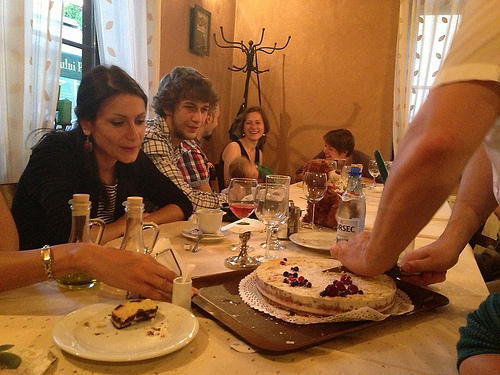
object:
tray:
[190, 266, 449, 352]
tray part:
[395, 278, 449, 314]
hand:
[47, 243, 199, 303]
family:
[1, 0, 500, 375]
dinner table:
[1, 172, 498, 375]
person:
[330, 0, 500, 287]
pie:
[256, 256, 397, 318]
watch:
[41, 244, 55, 281]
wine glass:
[254, 183, 289, 263]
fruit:
[283, 271, 312, 289]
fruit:
[320, 275, 364, 298]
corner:
[163, 3, 296, 182]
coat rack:
[213, 26, 292, 110]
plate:
[52, 298, 199, 362]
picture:
[197, 10, 209, 52]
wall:
[161, 3, 392, 167]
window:
[1, 0, 147, 182]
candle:
[56, 98, 72, 124]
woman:
[10, 64, 193, 251]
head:
[74, 65, 148, 164]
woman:
[219, 105, 272, 193]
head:
[244, 111, 266, 140]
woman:
[296, 128, 385, 184]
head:
[323, 127, 355, 161]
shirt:
[9, 126, 193, 251]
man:
[139, 65, 247, 214]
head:
[158, 66, 209, 140]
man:
[172, 88, 221, 192]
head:
[198, 86, 220, 136]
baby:
[229, 155, 275, 181]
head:
[230, 156, 259, 179]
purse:
[228, 45, 267, 150]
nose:
[192, 109, 203, 123]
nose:
[126, 119, 140, 141]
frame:
[188, 3, 213, 58]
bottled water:
[336, 167, 366, 242]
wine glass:
[226, 177, 261, 251]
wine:
[230, 204, 257, 220]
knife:
[322, 266, 420, 276]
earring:
[82, 134, 93, 154]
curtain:
[1, 0, 63, 183]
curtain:
[93, 0, 161, 121]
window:
[407, 12, 460, 123]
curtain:
[392, 0, 466, 158]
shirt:
[141, 115, 231, 214]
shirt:
[173, 137, 211, 187]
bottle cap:
[349, 167, 362, 180]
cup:
[190, 209, 223, 234]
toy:
[302, 157, 359, 230]